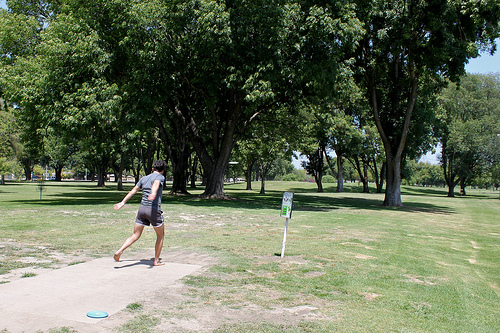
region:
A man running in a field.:
[99, 140, 184, 271]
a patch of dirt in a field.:
[0, 239, 235, 329]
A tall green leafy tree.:
[251, 8, 469, 210]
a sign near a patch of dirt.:
[257, 166, 308, 291]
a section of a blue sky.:
[464, 28, 498, 85]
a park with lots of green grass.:
[0, 165, 499, 330]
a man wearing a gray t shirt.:
[130, 165, 172, 205]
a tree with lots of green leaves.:
[347, 10, 483, 213]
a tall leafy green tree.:
[61, 0, 253, 194]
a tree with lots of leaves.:
[1, 0, 120, 180]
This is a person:
[108, 160, 177, 270]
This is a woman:
[101, 156, 191, 276]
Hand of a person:
[146, 174, 161, 207]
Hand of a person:
[98, 170, 147, 212]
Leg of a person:
[151, 212, 170, 270]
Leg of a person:
[111, 213, 147, 265]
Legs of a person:
[110, 210, 167, 265]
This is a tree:
[350, 0, 480, 216]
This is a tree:
[324, 103, 349, 204]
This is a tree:
[299, 113, 334, 209]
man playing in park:
[106, 149, 183, 293]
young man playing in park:
[98, 149, 184, 288]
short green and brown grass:
[317, 200, 366, 240]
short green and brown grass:
[292, 245, 352, 288]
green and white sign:
[273, 182, 294, 222]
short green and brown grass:
[207, 287, 291, 325]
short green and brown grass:
[316, 237, 364, 273]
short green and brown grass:
[367, 252, 423, 315]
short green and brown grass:
[406, 208, 476, 245]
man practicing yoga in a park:
[113, 158, 166, 267]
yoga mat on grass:
[1, 256, 201, 321]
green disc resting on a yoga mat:
[86, 308, 111, 317]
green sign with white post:
[276, 188, 294, 258]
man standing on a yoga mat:
[0, 160, 207, 318]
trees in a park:
[1, 18, 498, 200]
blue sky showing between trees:
[464, 35, 499, 75]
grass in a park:
[331, 211, 494, 326]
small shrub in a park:
[31, 183, 51, 199]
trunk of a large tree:
[381, 133, 403, 208]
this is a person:
[110, 143, 190, 279]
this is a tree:
[350, 111, 372, 190]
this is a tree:
[357, 2, 495, 213]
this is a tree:
[438, 62, 495, 202]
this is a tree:
[298, 90, 328, 195]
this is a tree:
[328, 90, 381, 195]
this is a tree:
[0, 25, 50, 190]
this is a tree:
[22, 36, 109, 187]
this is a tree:
[63, 37, 143, 195]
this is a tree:
[153, 0, 260, 206]